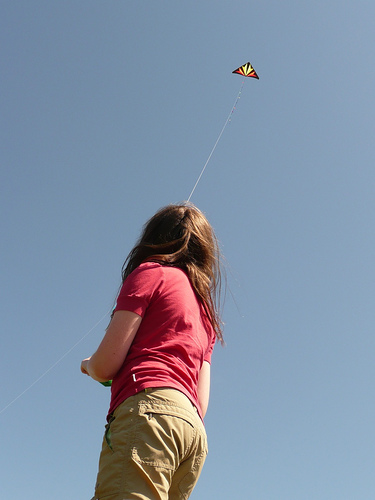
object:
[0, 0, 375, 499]
blue sky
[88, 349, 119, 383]
elbow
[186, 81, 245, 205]
string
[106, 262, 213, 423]
red shirt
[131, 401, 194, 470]
pocket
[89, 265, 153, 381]
arm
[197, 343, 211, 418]
arm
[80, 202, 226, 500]
girl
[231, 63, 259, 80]
girl kite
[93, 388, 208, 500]
brown pants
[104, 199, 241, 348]
hair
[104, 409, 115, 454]
pocket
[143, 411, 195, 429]
zipper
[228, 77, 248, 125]
tail